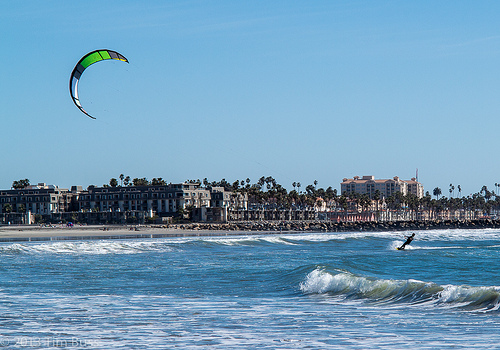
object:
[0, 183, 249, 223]
buildings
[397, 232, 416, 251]
wakeboarder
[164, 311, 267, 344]
ripple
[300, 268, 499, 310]
white wave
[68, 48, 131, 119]
kite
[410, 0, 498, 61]
sky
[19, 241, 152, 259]
foam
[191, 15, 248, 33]
white cloud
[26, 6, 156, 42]
blue sky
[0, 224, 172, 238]
sand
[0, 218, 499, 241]
beach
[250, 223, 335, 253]
wave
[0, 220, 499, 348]
ocean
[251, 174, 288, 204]
trees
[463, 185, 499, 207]
trees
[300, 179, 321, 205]
trees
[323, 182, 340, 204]
trees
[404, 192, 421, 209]
trees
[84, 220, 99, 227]
patch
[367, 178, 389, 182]
red roof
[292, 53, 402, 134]
blue sky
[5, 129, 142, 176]
sky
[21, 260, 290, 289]
blue water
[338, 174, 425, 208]
building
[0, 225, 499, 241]
line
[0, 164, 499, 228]
city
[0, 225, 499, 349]
water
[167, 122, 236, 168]
sky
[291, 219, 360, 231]
rocks